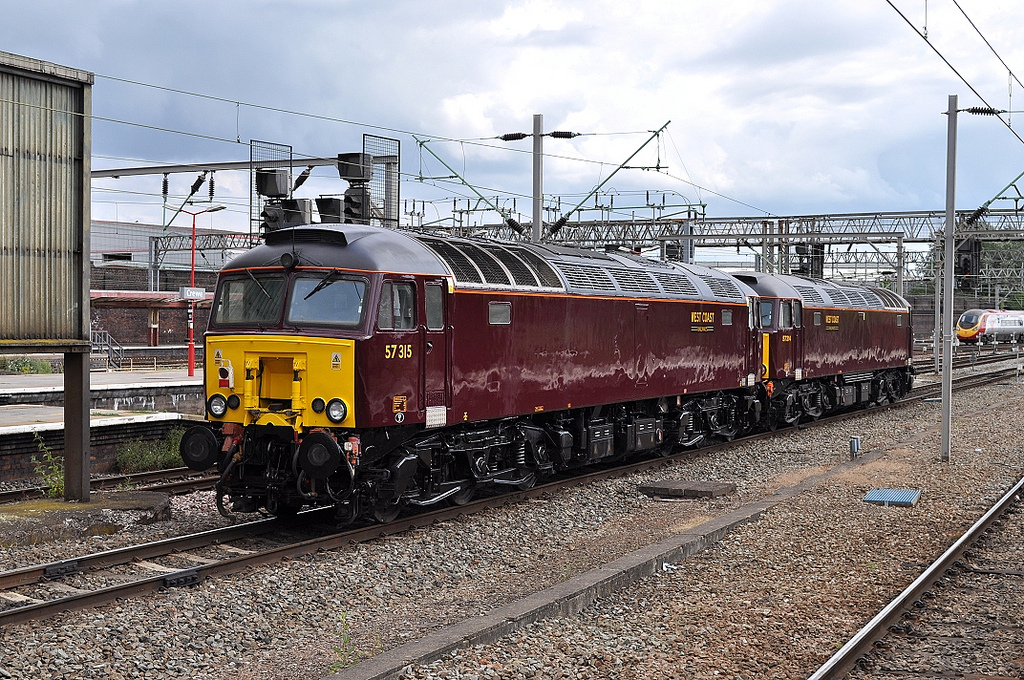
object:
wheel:
[532, 445, 557, 474]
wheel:
[548, 425, 573, 460]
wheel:
[769, 400, 785, 412]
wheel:
[799, 384, 834, 417]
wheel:
[876, 379, 903, 406]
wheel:
[896, 372, 912, 386]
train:
[202, 223, 916, 528]